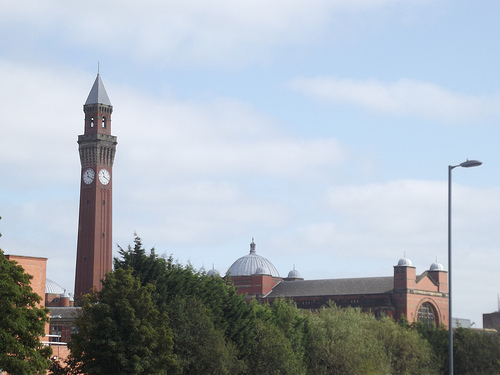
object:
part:
[296, 75, 356, 106]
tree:
[0, 247, 65, 375]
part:
[13, 257, 38, 315]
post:
[445, 156, 488, 375]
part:
[447, 158, 485, 209]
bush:
[65, 230, 316, 375]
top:
[102, 232, 170, 278]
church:
[72, 58, 454, 349]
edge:
[141, 248, 451, 332]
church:
[73, 58, 119, 312]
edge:
[71, 137, 84, 307]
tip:
[82, 59, 115, 108]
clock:
[82, 167, 96, 186]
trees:
[172, 327, 180, 373]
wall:
[3, 253, 49, 375]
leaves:
[225, 318, 238, 328]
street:
[245, 158, 500, 375]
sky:
[0, 0, 500, 330]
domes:
[286, 264, 304, 279]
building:
[196, 236, 449, 330]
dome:
[222, 243, 282, 278]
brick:
[394, 268, 452, 330]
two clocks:
[82, 167, 111, 186]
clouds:
[127, 10, 145, 26]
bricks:
[424, 284, 430, 290]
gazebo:
[77, 102, 117, 143]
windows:
[101, 115, 106, 128]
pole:
[445, 160, 455, 375]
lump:
[223, 235, 282, 278]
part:
[3, 0, 466, 243]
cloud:
[250, 72, 500, 140]